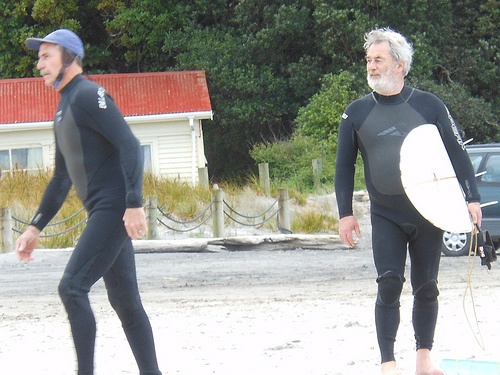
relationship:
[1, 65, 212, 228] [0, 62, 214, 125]
house with roof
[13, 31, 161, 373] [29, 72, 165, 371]
man wearing swim suit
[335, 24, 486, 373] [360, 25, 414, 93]
man with hair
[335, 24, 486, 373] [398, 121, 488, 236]
man holding surf board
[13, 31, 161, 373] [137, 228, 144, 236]
man wearing ring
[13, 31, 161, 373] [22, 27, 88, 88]
man wearing hat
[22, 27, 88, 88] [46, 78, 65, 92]
hat straps under chin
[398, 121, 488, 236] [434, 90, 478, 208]
surf board under arm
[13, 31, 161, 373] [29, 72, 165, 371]
man in swim suit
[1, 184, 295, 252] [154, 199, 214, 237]
fence with links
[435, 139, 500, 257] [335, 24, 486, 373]
car behind man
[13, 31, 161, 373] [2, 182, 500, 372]
man walking towards beach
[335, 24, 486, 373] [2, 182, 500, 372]
man walking towards beach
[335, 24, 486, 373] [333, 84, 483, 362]
man wearing wet suit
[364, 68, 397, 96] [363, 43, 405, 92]
beard on face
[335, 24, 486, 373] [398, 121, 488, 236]
man holding board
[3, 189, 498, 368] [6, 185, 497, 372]
sand on ground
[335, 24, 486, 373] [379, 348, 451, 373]
man with feet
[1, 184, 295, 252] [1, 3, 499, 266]
fence in background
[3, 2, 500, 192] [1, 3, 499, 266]
trees in background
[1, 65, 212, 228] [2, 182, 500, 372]
house on beach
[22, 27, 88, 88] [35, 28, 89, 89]
hat on head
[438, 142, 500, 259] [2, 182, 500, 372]
vehicle on beach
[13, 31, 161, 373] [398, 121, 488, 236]
man carrying surf board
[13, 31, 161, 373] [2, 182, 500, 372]
man on beach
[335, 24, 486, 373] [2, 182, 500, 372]
man on beach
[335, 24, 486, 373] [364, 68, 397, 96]
man with beard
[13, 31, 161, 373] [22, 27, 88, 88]
man with hat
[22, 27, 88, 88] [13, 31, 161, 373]
hat on man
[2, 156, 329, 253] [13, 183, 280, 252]
poles with barriers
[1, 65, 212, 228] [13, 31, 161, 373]
house behind man